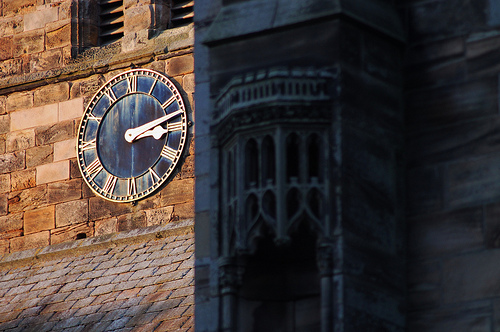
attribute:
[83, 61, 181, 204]
clock — black, large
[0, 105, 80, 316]
wall — brick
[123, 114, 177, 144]
hands — pointed, gold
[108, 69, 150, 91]
numerals — 9, roman, gold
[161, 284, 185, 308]
shingles — brown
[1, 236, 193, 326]
roof — reflected, shaded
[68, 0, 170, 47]
windows — small, decorative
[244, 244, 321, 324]
entrance — gated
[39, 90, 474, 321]
building — brown, shaded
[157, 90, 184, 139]
time — 3:13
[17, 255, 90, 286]
bricks — gray